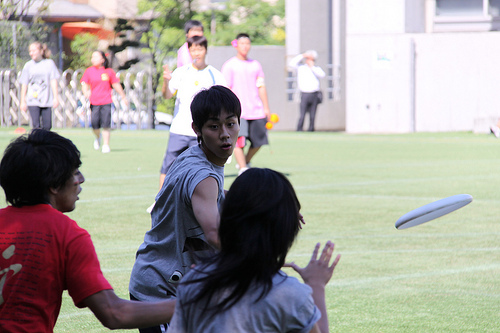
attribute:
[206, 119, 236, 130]
man's eyes —  man's,  open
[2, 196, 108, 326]
shirt — red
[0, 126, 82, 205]
hair — black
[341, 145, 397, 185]
green grass —  field ,  green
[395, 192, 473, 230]
frisbee — white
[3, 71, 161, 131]
fence — wooden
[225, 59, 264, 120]
shirt — pink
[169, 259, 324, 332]
shirt — red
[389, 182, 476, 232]
frisbee — white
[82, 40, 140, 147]
women — red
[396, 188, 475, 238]
frisbee — white